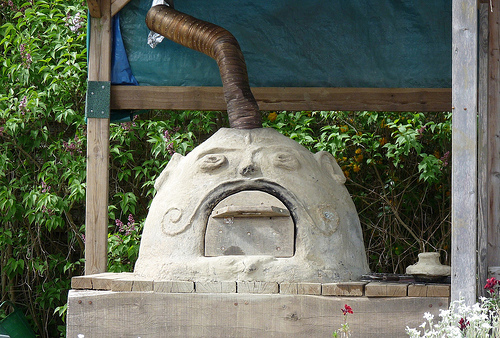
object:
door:
[205, 190, 294, 257]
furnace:
[132, 5, 370, 284]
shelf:
[64, 273, 451, 338]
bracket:
[85, 81, 111, 119]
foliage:
[0, 1, 452, 216]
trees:
[263, 110, 451, 276]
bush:
[0, 0, 230, 338]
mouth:
[202, 186, 296, 259]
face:
[134, 129, 363, 281]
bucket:
[0, 300, 38, 337]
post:
[84, 14, 111, 275]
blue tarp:
[87, 0, 453, 88]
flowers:
[402, 277, 498, 338]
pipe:
[145, 4, 262, 129]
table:
[77, 264, 457, 282]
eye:
[197, 153, 226, 170]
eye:
[273, 152, 300, 170]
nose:
[239, 151, 258, 176]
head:
[132, 128, 371, 286]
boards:
[70, 271, 451, 296]